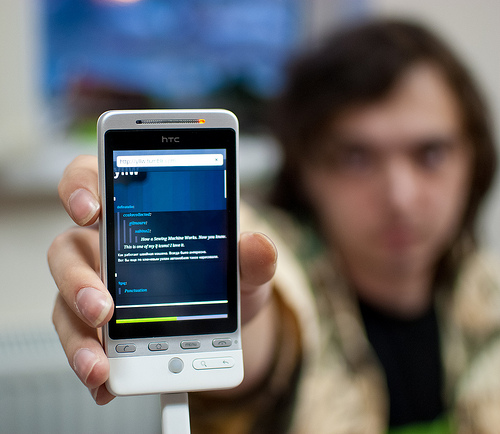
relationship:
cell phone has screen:
[97, 104, 244, 399] [109, 129, 233, 331]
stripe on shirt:
[390, 412, 447, 433] [359, 299, 440, 422]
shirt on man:
[359, 299, 440, 422] [43, 13, 498, 433]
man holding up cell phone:
[43, 13, 498, 433] [97, 104, 244, 399]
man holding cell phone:
[43, 13, 498, 433] [97, 104, 244, 399]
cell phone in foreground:
[97, 104, 244, 399] [3, 103, 499, 428]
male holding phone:
[43, 13, 498, 433] [101, 106, 249, 396]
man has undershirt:
[43, 13, 498, 433] [364, 304, 449, 407]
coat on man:
[160, 204, 499, 429] [43, 13, 498, 433]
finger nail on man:
[76, 283, 117, 329] [43, 13, 498, 433]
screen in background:
[36, 11, 313, 107] [9, 15, 491, 427]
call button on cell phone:
[166, 358, 185, 376] [97, 104, 244, 399]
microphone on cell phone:
[135, 118, 206, 125] [97, 104, 244, 399]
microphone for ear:
[135, 118, 206, 125] [275, 118, 314, 203]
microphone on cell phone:
[134, 114, 205, 125] [97, 104, 244, 399]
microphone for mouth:
[134, 114, 205, 125] [366, 217, 434, 248]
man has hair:
[43, 13, 498, 433] [268, 15, 500, 238]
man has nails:
[43, 13, 498, 433] [68, 183, 116, 403]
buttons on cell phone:
[114, 338, 235, 355] [97, 107, 244, 397]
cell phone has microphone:
[97, 107, 244, 397] [135, 118, 206, 125]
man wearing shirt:
[43, 13, 498, 433] [359, 299, 440, 422]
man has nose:
[43, 13, 498, 433] [379, 151, 423, 222]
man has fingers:
[43, 13, 498, 433] [45, 149, 281, 401]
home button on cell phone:
[161, 356, 186, 380] [97, 107, 244, 397]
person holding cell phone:
[43, 13, 498, 433] [97, 104, 244, 399]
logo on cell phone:
[159, 134, 180, 146] [97, 104, 244, 399]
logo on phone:
[159, 134, 180, 146] [101, 106, 249, 396]